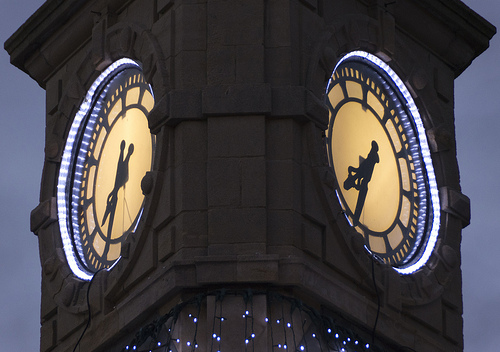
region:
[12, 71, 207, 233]
yellow face of clock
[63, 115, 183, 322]
clock has black hands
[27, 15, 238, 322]
frame of clock is brown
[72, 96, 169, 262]
clock uses black hash marks for time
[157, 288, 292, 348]
blue points of light under clock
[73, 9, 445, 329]
clock tower is large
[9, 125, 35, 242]
sky is dark blue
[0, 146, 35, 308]
sky is overcast and cloudy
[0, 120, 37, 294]
clouds dim the sky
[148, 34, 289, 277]
clock tower is grey brick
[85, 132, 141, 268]
the hands of a clock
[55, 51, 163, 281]
the face of a clock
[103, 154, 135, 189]
the center of a clock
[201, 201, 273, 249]
a brick in the wall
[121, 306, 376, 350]
blue lights on the tower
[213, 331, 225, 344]
a small blue light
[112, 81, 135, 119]
a notch on the clock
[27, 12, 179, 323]
the frame of a clock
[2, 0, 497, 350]
a large clock tower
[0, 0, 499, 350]
a blue sky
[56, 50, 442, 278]
two clocks on the sides of a tower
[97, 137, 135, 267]
black hour and minute hands on the tower clock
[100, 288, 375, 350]
blue Christmas lights around the clock tower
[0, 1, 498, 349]
the top of a tower clock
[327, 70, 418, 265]
clock with a yellow face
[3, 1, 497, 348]
a black clock tower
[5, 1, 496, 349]
a black clock tower on top of a building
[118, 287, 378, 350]
lights on the tower below the clocks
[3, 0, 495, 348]
a black clock tower with lights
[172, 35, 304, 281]
black stones on the clock tower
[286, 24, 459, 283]
the clock is lit up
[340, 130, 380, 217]
the hands are black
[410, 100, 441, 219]
the lights are bright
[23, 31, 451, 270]
there is 2 clocks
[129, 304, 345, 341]
little round lights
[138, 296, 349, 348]
lights hanging from strings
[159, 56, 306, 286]
the building is a dark color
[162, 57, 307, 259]
the building is made of bricks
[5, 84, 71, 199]
it is getting dark out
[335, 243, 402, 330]
a black wire coming from the clock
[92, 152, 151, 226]
Clock has black hands.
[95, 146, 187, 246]
Clock has yellow face.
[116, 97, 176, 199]
Clock has black numbers.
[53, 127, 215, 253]
Clock is round in shape.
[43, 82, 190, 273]
Clock is inside of tall tower.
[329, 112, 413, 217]
Clock has black hands.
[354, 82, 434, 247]
Clock has yellow face.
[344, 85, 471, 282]
Clock has black numbers.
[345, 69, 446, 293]
Clock is round in shape.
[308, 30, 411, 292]
Clock is inside of tower.